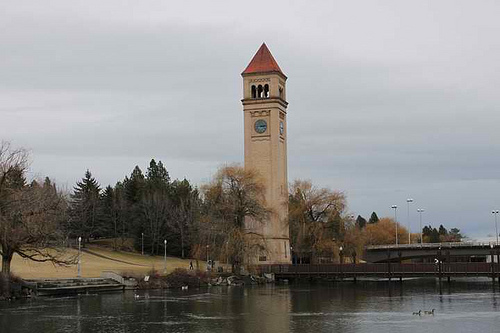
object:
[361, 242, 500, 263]
bridge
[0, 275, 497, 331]
lake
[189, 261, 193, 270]
man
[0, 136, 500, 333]
park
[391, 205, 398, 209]
street lights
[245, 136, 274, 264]
wall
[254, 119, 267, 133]
clock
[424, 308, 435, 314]
ducks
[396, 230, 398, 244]
bottom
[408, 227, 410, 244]
bottom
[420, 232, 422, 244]
bottom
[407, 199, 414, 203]
lamp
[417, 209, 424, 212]
lamp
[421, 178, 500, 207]
white clouds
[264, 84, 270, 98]
window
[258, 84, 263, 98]
window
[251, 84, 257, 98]
window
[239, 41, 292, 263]
building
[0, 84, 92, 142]
clouds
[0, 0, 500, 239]
sky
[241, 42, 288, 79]
roof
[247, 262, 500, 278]
bridge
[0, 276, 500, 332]
water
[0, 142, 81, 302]
brown tree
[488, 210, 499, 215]
lamps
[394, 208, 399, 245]
poles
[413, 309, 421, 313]
ducks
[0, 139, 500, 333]
around